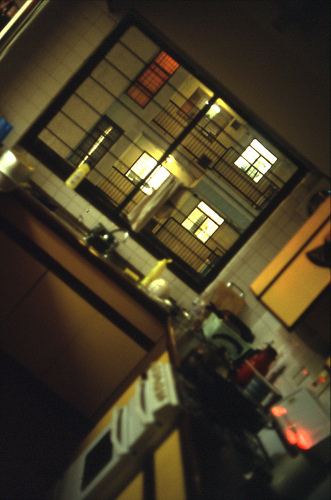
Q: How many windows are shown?
A: 7.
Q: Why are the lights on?
A: It's night time.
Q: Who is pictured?
A: No one.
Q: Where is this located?
A: The kitchen.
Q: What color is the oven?
A: White.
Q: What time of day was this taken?
A: Night time.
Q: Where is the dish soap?
A: By the sing.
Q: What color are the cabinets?
A: Yellow.